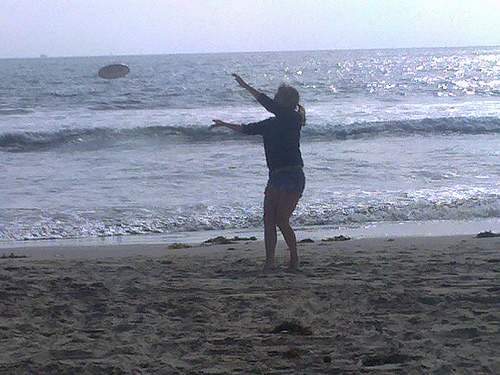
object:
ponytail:
[292, 102, 305, 126]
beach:
[2, 15, 499, 372]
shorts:
[265, 170, 304, 193]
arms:
[242, 83, 278, 114]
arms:
[224, 118, 263, 135]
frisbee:
[93, 63, 133, 77]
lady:
[206, 72, 306, 272]